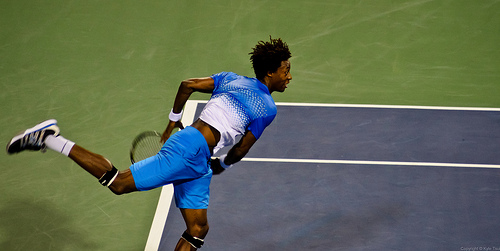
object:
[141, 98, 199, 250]
line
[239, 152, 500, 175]
line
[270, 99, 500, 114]
line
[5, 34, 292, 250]
tennis player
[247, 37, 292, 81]
hair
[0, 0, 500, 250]
tennis court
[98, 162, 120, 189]
band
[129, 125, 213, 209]
shorts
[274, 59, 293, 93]
face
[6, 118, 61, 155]
shoe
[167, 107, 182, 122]
wristband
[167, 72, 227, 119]
arm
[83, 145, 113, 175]
leg muscle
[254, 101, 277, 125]
shoulder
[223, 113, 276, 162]
arm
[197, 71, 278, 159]
shirt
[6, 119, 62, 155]
foot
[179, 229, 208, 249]
band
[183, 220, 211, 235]
knee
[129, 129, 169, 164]
racket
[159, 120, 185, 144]
hand